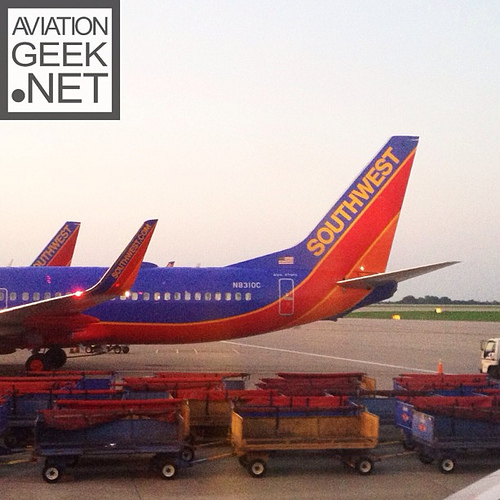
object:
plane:
[0, 134, 456, 367]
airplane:
[0, 132, 463, 365]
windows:
[173, 292, 181, 301]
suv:
[29, 412, 203, 483]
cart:
[230, 405, 380, 473]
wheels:
[355, 456, 373, 476]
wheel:
[247, 458, 268, 479]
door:
[277, 277, 296, 315]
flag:
[278, 254, 294, 265]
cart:
[391, 395, 493, 473]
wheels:
[437, 452, 454, 474]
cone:
[434, 356, 446, 379]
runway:
[1, 312, 498, 499]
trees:
[421, 286, 452, 304]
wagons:
[24, 385, 191, 465]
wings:
[0, 219, 167, 333]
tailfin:
[299, 129, 422, 274]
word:
[304, 145, 404, 258]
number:
[229, 281, 262, 288]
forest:
[356, 276, 500, 325]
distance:
[0, 211, 499, 345]